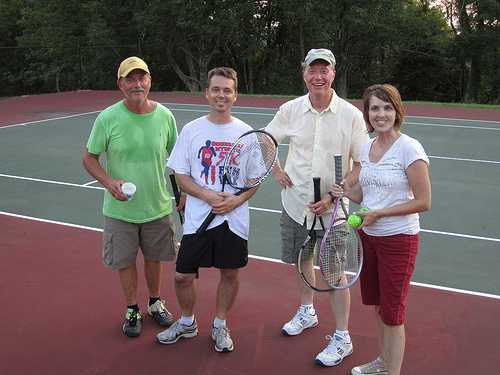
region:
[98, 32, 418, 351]
group of people on tennis court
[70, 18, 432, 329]
people posing for picture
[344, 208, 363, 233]
yellow tennis ball in hand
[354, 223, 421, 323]
red shorts on woman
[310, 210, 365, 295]
pink and white racket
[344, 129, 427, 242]
white top on woman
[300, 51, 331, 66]
green hat on head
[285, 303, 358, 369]
white shoes on feet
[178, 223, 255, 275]
black shorts on man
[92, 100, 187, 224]
green shirt on man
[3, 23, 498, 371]
a family on the tennis court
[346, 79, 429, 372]
a woman is standing far left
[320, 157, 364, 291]
woman far left; holding ball and tennis racket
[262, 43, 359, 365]
older gentleman standing next to woman on far left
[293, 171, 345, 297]
older gentleman near woman holds tennis racket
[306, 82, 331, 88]
older man near woman is smiling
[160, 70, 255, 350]
younger male stands between two older males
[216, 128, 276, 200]
younger male holds tennis racket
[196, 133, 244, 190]
younger male has shirt advertise a running event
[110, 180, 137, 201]
older male far right holds cup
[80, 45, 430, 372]
the people standing on the tennis court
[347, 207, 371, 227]
the tennis balls in the woman's hand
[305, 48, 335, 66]
the hat on the man's head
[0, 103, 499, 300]
the white lines on the court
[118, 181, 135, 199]
the cup in the man's hand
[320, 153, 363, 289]
the tennis racquet in the woman's hand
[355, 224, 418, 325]
the red shorts on the woman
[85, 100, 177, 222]
the man's green short sleeved shirt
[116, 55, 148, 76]
the hat on the man's head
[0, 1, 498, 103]
the trees lining the tennis court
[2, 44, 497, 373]
Four people standing on a tennis court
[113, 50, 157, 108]
Yellow hat on man's head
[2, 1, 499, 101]
Green trees in the background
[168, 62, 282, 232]
Man holding a tennis racket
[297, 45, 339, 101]
The man is smiling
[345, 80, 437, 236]
Woman holding a tennis ball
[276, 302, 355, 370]
A pair of white sneakers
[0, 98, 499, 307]
White lines on the court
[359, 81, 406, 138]
Woman has brown hair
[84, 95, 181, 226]
A shirt is green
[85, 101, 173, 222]
the shirt is green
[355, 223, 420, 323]
the capris are red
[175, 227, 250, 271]
the shorts are black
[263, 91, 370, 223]
the yellow shirt has a collar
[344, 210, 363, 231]
the ball is green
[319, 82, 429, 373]
the woman is holding a tennis racket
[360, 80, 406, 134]
the woman has brown hair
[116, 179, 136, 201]
the man is holding a cup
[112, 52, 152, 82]
the hat is yellow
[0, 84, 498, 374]
the court is red and green